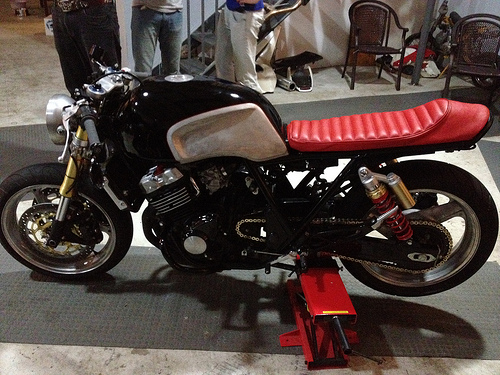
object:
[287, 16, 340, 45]
wall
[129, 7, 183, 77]
jean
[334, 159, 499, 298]
tire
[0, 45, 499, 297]
black motorcycle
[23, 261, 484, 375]
shadow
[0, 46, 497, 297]
bike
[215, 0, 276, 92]
person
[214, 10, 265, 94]
pants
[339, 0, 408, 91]
chair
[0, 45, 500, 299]
jet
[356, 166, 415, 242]
absorption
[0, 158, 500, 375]
pavement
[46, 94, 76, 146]
headlight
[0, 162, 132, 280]
front wheel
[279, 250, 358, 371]
motorcycle ramp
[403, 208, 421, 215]
spoke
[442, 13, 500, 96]
chair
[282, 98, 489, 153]
seat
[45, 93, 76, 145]
light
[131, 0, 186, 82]
person